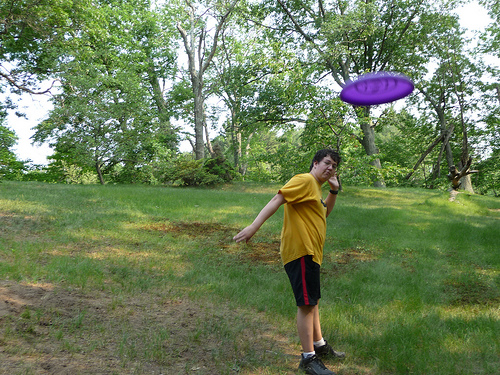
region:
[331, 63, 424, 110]
the frisbee is purple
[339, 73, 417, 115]
the frisbee is in the air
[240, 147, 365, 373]
he is from throwing the frisbee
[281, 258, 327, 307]
the shorts are black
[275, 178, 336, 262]
the short is yellow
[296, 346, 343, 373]
the shoes are black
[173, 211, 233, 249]
the ground is unpatched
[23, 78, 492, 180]
trees are in the background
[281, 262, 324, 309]
the strip is red in color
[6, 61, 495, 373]
the scene was taken outdoors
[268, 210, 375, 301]
man in black shorts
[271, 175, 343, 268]
man in black shorts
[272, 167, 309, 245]
man in black shorts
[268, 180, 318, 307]
man in black shorts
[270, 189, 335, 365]
man in black shorts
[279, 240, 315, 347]
man in black shorts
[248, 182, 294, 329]
man in black shorts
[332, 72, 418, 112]
FRISBEE IS PURPLE IN COLOR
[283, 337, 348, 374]
BOY IS WEARING BLACK SHOES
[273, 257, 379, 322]
PANTS HAVE A RED STRIPE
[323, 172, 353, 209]
BOY IS WEARING A WATCH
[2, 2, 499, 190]
TREES ARE IN THE BACKGROUND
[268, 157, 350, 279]
SHIRT IS YELLOW IN COLOR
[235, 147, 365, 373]
BOY IS FACING TO THE RIGHT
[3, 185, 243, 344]
GRASS IS OF GREEN IN COLOR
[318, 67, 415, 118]
FRISBEE IS IN MID AIR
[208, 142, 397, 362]
BOY IS PLAYING WITH THE FRISBEE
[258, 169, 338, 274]
baggy yellow tee shirt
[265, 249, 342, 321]
black shorts with red stripe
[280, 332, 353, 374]
pair of black and grey shoes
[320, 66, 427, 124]
bright purple flying disk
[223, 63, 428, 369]
boy throwing purple frisbee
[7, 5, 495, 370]
boy playing in a field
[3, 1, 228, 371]
large field with trees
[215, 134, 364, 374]
boy posing in yellow shirt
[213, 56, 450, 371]
boy plays with a flying disk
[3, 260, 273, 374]
large spot of dead grass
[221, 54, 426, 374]
The man just tossed a frisbee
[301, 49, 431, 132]
The frisbee is in flight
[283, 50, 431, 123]
The frisbee is bright purple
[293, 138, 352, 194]
The man has dark hair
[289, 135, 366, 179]
The man's hair is brown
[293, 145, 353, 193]
The man's hair is straight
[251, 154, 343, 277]
The man is wearing a yellow T shirt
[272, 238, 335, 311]
The man is wearing black shorts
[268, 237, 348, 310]
The man's shorts have a red stripe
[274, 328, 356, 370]
The man is wearing black shoes